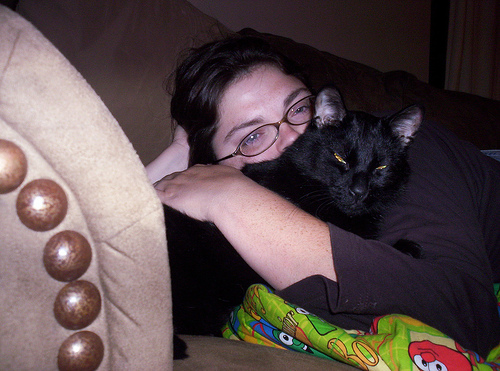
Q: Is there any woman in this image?
A: Yes, there is a woman.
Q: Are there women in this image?
A: Yes, there is a woman.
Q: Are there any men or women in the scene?
A: Yes, there is a woman.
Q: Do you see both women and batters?
A: No, there is a woman but no batters.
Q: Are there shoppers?
A: No, there are no shoppers.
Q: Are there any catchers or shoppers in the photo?
A: No, there are no shoppers or catchers.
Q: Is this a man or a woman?
A: This is a woman.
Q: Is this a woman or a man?
A: This is a woman.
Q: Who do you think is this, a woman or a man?
A: This is a woman.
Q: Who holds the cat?
A: The woman holds the cat.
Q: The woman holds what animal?
A: The woman holds the cat.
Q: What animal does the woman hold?
A: The woman holds the cat.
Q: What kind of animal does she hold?
A: The woman holds the cat.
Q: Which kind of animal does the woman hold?
A: The woman holds the cat.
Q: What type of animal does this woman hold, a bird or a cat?
A: The woman holds a cat.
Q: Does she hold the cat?
A: Yes, the woman holds the cat.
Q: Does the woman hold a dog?
A: No, the woman holds the cat.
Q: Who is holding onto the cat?
A: The woman is holding onto the cat.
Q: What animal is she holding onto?
A: The woman is holding onto the cat.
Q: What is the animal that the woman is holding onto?
A: The animal is a cat.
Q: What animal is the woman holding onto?
A: The woman is holding onto the cat.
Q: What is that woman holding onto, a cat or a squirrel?
A: The woman is holding onto a cat.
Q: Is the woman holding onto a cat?
A: Yes, the woman is holding onto a cat.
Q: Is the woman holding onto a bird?
A: No, the woman is holding onto a cat.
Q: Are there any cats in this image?
A: Yes, there is a cat.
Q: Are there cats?
A: Yes, there is a cat.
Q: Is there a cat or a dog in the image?
A: Yes, there is a cat.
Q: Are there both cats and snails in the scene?
A: No, there is a cat but no snails.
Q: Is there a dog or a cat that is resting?
A: Yes, the cat is resting.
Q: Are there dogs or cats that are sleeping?
A: Yes, the cat is sleeping.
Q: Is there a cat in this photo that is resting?
A: Yes, there is a cat that is resting.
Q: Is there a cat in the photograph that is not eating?
A: Yes, there is a cat that is resting.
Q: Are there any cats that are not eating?
A: Yes, there is a cat that is resting.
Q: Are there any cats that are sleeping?
A: Yes, there is a cat that is sleeping.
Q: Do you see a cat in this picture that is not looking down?
A: Yes, there is a cat that is sleeping .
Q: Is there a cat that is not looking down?
A: Yes, there is a cat that is sleeping.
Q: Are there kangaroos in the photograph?
A: No, there are no kangaroos.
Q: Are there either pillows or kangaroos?
A: No, there are no kangaroos or pillows.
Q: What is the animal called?
A: The animal is a cat.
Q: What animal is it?
A: The animal is a cat.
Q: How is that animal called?
A: This is a cat.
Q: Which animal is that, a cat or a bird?
A: This is a cat.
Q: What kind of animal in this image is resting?
A: The animal is a cat.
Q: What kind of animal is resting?
A: The animal is a cat.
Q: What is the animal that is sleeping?
A: The animal is a cat.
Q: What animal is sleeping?
A: The animal is a cat.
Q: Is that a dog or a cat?
A: That is a cat.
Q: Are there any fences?
A: No, there are no fences.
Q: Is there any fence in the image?
A: No, there are no fences.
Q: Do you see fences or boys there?
A: No, there are no fences or boys.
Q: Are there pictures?
A: No, there are no pictures.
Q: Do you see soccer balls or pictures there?
A: No, there are no pictures or soccer balls.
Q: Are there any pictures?
A: No, there are no pictures.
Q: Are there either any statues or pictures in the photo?
A: No, there are no pictures or statues.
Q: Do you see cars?
A: No, there are no cars.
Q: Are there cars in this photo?
A: No, there are no cars.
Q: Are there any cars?
A: No, there are no cars.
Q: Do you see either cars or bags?
A: No, there are no cars or bags.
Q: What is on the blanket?
A: The character is on the blanket.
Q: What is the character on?
A: The character is on the blanket.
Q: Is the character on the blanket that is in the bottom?
A: Yes, the character is on the blanket.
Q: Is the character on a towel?
A: No, the character is on the blanket.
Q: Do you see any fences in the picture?
A: No, there are no fences.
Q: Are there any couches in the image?
A: Yes, there is a couch.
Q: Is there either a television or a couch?
A: Yes, there is a couch.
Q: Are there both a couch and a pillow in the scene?
A: No, there is a couch but no pillows.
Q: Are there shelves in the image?
A: No, there are no shelves.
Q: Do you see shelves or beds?
A: No, there are no shelves or beds.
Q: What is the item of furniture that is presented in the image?
A: The piece of furniture is a couch.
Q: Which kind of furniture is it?
A: The piece of furniture is a couch.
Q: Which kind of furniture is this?
A: This is a couch.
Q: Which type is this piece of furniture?
A: This is a couch.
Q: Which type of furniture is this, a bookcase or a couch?
A: This is a couch.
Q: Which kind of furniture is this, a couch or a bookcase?
A: This is a couch.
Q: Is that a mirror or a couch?
A: That is a couch.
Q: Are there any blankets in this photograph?
A: Yes, there is a blanket.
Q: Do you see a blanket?
A: Yes, there is a blanket.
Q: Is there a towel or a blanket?
A: Yes, there is a blanket.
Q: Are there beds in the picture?
A: No, there are no beds.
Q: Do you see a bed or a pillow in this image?
A: No, there are no beds or pillows.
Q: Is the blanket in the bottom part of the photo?
A: Yes, the blanket is in the bottom of the image.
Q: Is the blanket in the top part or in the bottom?
A: The blanket is in the bottom of the image.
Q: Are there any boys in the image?
A: No, there are no boys.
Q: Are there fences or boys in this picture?
A: No, there are no boys or fences.